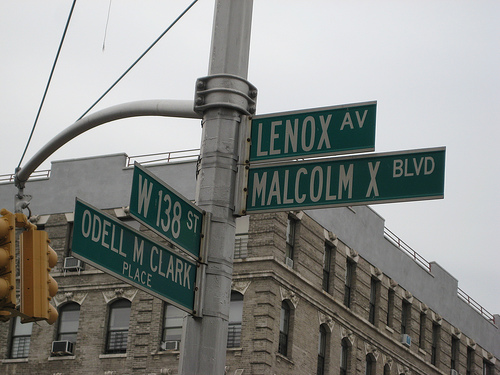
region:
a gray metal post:
[165, 0, 256, 366]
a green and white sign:
[237, 150, 447, 215]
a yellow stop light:
[1, 180, 61, 335]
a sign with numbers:
[127, 170, 207, 255]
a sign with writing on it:
[235, 150, 446, 212]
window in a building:
[270, 215, 350, 370]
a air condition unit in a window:
[45, 335, 77, 360]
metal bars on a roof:
[385, 222, 437, 267]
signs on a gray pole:
[66, 30, 441, 371]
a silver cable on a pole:
[42, 0, 196, 114]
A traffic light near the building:
[0, 213, 57, 323]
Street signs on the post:
[71, 113, 448, 310]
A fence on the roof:
[378, 225, 494, 320]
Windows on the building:
[280, 297, 330, 374]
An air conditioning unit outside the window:
[48, 340, 77, 355]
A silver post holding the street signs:
[174, 3, 251, 374]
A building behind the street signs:
[1, 143, 496, 373]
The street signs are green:
[67, 168, 206, 310]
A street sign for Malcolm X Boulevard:
[249, 153, 444, 202]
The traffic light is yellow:
[1, 202, 56, 319]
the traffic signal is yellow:
[2, 205, 63, 330]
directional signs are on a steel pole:
[68, 96, 448, 331]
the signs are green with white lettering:
[70, 101, 446, 312]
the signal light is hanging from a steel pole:
[2, 94, 211, 329]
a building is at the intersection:
[6, 138, 496, 374]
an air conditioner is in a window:
[46, 333, 79, 356]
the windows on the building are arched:
[26, 285, 349, 372]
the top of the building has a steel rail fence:
[5, 144, 499, 342]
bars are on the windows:
[9, 315, 244, 362]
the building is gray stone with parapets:
[239, 213, 335, 373]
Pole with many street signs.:
[164, 3, 273, 363]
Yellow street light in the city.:
[1, 184, 66, 325]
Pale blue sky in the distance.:
[324, 22, 451, 79]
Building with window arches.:
[263, 290, 302, 372]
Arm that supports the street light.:
[18, 86, 196, 196]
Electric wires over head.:
[52, 3, 202, 105]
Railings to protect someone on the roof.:
[366, 223, 438, 283]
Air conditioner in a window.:
[46, 337, 80, 364]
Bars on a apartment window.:
[102, 327, 130, 358]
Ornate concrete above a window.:
[266, 289, 308, 309]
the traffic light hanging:
[0, 184, 59, 325]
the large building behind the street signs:
[0, 148, 499, 374]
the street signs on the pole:
[69, 102, 447, 313]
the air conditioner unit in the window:
[51, 340, 73, 355]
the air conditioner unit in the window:
[160, 340, 177, 352]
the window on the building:
[100, 297, 132, 354]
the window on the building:
[275, 298, 293, 363]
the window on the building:
[283, 211, 300, 266]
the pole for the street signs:
[175, 1, 252, 374]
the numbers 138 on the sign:
[155, 187, 180, 238]